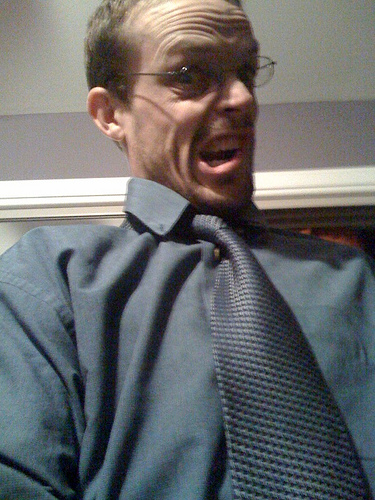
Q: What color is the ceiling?
A: Gray.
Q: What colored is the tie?
A: Blue and black.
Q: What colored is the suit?
A: Blue.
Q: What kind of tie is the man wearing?
A: Blue.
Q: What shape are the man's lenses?
A: Circle.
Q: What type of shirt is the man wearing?
A: Dress.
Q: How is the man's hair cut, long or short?
A: Short.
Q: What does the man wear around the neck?
A: Tie.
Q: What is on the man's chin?
A: Stubble.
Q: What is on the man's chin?
A: Facial hair.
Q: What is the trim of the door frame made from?
A: Wood.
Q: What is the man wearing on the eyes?
A: Glasses.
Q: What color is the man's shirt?
A: Blue.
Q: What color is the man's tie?
A: Blue.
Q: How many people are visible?
A: One.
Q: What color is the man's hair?
A: Light brown.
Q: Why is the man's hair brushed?
A: He wanted to look professional.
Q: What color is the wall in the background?
A: Gray.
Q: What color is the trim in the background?
A: White.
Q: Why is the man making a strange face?
A: To be funny.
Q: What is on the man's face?
A: Glasses.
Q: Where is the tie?
A: Around the man's neck.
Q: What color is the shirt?
A: Blue.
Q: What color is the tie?
A: Blue.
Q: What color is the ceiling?
A: White.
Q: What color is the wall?
A: Grey.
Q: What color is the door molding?
A: White.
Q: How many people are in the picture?
A: 1.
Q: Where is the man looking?
A: At the camera.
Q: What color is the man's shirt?
A: Blue.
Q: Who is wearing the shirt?
A: A man.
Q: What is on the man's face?
A: Glasses.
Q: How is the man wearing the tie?
A: Around his neck.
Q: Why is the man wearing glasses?
A: To see.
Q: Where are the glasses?
A: On the man's face.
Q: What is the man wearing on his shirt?
A: A tie.